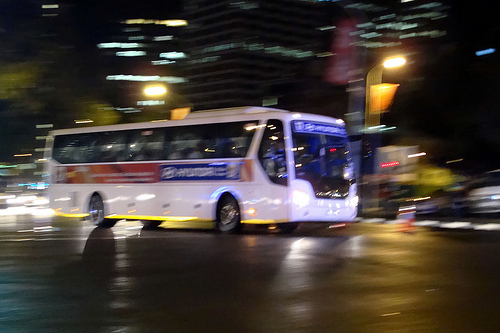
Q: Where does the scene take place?
A: On a city street.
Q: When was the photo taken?
A: Night.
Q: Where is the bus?
A: In the street.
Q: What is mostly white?
A: A bus.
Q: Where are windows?
A: On a bus.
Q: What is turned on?
A: Street lights.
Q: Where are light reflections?
A: On the ground.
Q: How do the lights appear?
A: Blurry.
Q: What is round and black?
A: Tires.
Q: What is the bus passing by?
A: Buildings.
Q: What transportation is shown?
A: Bus.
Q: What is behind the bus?
A: Buildings.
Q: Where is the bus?
A: Road.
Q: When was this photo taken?
A: At night.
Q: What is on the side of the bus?
A: Advertisements.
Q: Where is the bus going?
A: Right.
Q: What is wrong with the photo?
A: Blurry.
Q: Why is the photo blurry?
A: Too much motion.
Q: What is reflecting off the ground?
A: Lights.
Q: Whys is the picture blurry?
A: Because of the motion?.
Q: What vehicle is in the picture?
A: A bus.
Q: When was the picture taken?
A: At night.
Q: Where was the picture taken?
A: On a city street.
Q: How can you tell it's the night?
A: The street lights are on.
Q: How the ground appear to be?
A: Wet.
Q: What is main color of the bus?
A: White.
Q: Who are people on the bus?
A: Passengers.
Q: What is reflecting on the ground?
A: Lights.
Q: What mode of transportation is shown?
A: Bus.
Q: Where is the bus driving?
A: On the road.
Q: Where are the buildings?
A: Background.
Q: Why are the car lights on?
A: Its night.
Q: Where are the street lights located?
A: Along side of street.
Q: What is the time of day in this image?
A: Night.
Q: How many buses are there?
A: 1.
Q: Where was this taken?
A: Street.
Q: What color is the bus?
A: White.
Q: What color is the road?
A: Black.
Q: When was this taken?
A: Night time.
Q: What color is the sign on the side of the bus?
A: Blue.